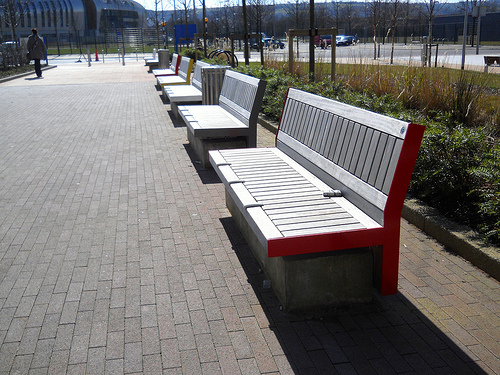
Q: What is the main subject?
A: Benches.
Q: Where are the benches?
A: Sidewalk.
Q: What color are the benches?
A: Brown.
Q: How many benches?
A: Six.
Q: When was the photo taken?
A: Day time.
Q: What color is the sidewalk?
A: Brown.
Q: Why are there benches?
A: To sit on.